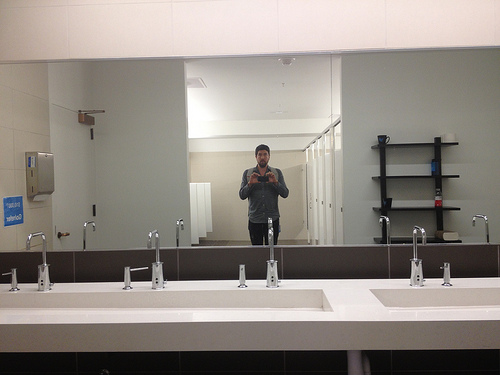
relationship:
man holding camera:
[240, 143, 288, 239] [253, 169, 280, 192]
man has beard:
[240, 143, 288, 239] [254, 158, 272, 165]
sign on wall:
[0, 193, 26, 223] [2, 68, 94, 262]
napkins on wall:
[20, 143, 55, 210] [2, 68, 94, 262]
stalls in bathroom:
[294, 132, 347, 240] [1, 4, 493, 360]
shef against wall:
[366, 130, 467, 245] [344, 53, 499, 240]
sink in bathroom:
[0, 266, 500, 353] [1, 4, 493, 360]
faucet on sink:
[27, 232, 54, 284] [0, 266, 500, 353]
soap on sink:
[3, 266, 18, 292] [0, 266, 500, 353]